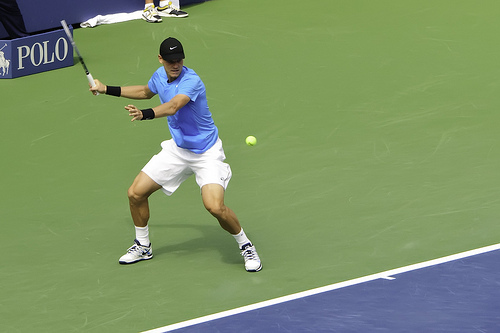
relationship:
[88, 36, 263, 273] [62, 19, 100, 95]
man swinging racket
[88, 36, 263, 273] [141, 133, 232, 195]
man wearing shorts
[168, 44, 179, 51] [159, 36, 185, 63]
nike logo on front of cap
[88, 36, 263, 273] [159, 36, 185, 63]
man wearing cap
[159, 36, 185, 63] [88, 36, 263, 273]
cap worn on man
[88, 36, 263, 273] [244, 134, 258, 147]
man addressing tennis ball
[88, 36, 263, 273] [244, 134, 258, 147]
man about to hit tennis ball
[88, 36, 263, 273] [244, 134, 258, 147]
man ready to hit tennis ball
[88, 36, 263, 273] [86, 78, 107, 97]
man has right hand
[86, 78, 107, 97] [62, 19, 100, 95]
right hand holding racket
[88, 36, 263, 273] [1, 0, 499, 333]
man has feet on tennis court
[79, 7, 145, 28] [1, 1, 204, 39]
towel laying against wall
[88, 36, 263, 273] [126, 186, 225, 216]
man has knees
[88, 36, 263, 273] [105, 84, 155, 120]
man wearing wristbands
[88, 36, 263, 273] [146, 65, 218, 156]
man wearing shirt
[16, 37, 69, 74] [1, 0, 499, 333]
polo advertisement on side of tennis court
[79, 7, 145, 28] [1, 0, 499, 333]
towel laying on tennis court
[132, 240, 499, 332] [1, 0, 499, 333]
boundary line part of tennis court